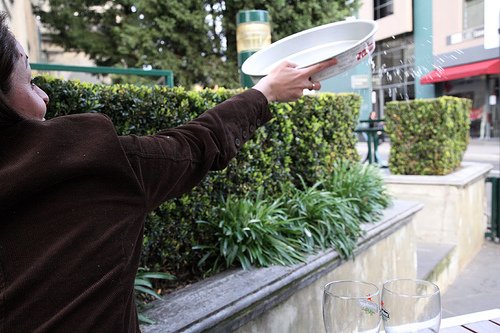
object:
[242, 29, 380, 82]
dish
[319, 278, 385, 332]
glasses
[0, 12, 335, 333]
person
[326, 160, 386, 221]
plants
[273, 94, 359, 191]
bushes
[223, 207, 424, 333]
wall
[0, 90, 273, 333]
jacket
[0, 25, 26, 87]
hair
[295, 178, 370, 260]
shrubs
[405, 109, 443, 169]
grass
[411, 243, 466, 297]
steps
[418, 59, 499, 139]
store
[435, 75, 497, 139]
front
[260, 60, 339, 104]
hand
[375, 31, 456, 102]
liquid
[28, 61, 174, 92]
handrail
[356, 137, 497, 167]
sidewalk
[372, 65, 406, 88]
window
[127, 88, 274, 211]
sleeves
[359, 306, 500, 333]
table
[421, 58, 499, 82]
awning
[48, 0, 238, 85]
tree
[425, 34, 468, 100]
water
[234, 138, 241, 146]
buttons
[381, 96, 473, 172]
bush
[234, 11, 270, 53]
light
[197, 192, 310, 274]
plants